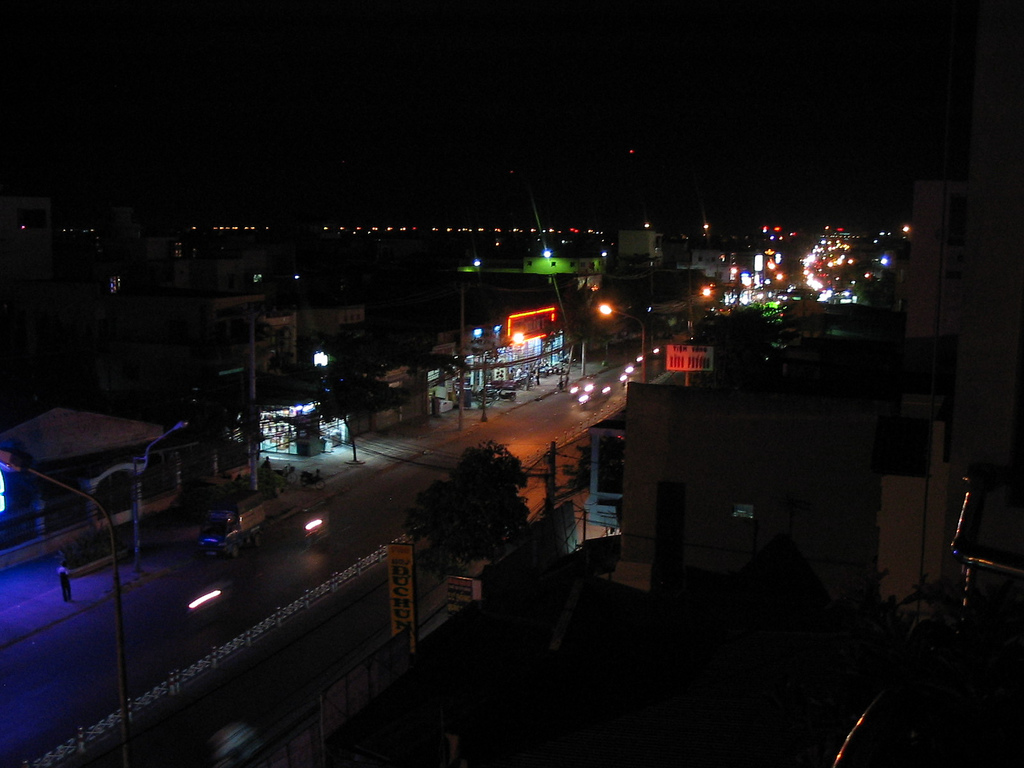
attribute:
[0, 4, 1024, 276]
sky — black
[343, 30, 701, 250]
sky — black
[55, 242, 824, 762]
road — paved, black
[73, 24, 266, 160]
sky — black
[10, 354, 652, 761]
road — black, paved